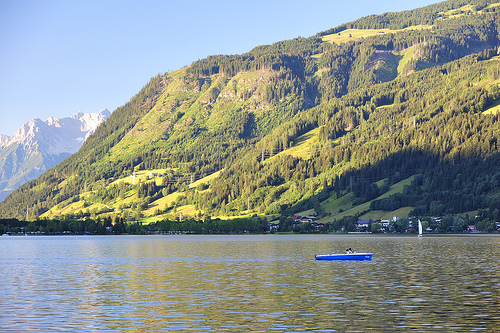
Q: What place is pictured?
A: It is a lake.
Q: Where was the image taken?
A: It was taken at the lake.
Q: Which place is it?
A: It is a lake.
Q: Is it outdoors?
A: Yes, it is outdoors.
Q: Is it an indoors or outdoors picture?
A: It is outdoors.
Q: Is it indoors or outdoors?
A: It is outdoors.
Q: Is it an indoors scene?
A: No, it is outdoors.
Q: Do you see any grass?
A: Yes, there is grass.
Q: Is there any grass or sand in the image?
A: Yes, there is grass.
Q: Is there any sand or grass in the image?
A: Yes, there is grass.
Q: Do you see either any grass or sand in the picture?
A: Yes, there is grass.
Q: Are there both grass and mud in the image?
A: No, there is grass but no mud.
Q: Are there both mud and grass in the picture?
A: No, there is grass but no mud.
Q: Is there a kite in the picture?
A: No, there are no kites.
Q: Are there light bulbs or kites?
A: No, there are no kites or light bulbs.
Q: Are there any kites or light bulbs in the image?
A: No, there are no kites or light bulbs.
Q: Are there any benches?
A: No, there are no benches.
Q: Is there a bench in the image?
A: No, there are no benches.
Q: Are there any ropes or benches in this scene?
A: No, there are no benches or ropes.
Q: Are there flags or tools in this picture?
A: No, there are no flags or tools.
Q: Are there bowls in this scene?
A: No, there are no bowls.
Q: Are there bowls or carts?
A: No, there are no bowls or carts.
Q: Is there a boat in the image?
A: Yes, there is a boat.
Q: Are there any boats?
A: Yes, there is a boat.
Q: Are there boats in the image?
A: Yes, there is a boat.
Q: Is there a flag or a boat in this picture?
A: Yes, there is a boat.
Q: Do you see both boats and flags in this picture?
A: No, there is a boat but no flags.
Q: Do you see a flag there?
A: No, there are no flags.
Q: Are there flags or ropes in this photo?
A: No, there are no flags or ropes.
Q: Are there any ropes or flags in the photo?
A: No, there are no flags or ropes.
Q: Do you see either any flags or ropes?
A: No, there are no flags or ropes.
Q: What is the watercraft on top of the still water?
A: The watercraft is a boat.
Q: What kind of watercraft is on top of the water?
A: The watercraft is a boat.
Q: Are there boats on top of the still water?
A: Yes, there is a boat on top of the water.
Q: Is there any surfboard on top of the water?
A: No, there is a boat on top of the water.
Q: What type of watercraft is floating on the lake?
A: The watercraft is a boat.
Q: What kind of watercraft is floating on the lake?
A: The watercraft is a boat.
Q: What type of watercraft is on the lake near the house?
A: The watercraft is a boat.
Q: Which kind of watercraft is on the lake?
A: The watercraft is a boat.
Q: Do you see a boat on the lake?
A: Yes, there is a boat on the lake.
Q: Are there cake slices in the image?
A: No, there are no cake slices.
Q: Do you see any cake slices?
A: No, there are no cake slices.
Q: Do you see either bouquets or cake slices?
A: No, there are no cake slices or bouquets.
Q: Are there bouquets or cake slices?
A: No, there are no cake slices or bouquets.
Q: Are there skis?
A: No, there are no skis.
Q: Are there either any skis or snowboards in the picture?
A: No, there are no skis or snowboards.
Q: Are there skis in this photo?
A: No, there are no skis.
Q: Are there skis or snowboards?
A: No, there are no skis or snowboards.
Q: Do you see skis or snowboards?
A: No, there are no skis or snowboards.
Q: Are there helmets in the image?
A: No, there are no helmets.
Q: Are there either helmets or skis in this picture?
A: No, there are no helmets or skis.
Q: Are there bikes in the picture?
A: No, there are no bikes.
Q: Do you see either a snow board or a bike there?
A: No, there are no bikes or snowboards.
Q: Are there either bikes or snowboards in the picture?
A: No, there are no bikes or snowboards.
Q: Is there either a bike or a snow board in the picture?
A: No, there are no bikes or snowboards.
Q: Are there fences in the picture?
A: No, there are no fences.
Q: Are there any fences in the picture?
A: No, there are no fences.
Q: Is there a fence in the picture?
A: No, there are no fences.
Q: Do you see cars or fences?
A: No, there are no fences or cars.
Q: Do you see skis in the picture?
A: No, there are no skis.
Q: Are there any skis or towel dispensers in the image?
A: No, there are no skis or towel dispensers.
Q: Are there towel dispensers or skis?
A: No, there are no skis or towel dispensers.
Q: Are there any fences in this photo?
A: No, there are no fences.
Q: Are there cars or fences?
A: No, there are no fences or cars.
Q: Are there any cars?
A: No, there are no cars.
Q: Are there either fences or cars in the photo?
A: No, there are no cars or fences.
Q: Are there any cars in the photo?
A: No, there are no cars.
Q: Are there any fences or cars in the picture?
A: No, there are no cars or fences.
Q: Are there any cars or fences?
A: No, there are no cars or fences.